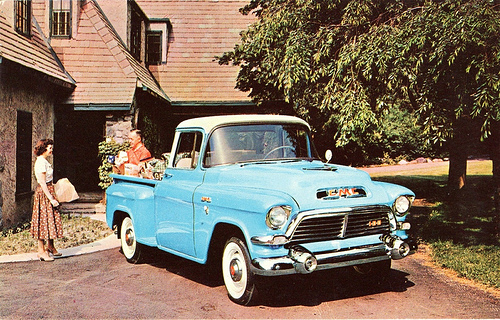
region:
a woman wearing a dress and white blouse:
[31, 135, 76, 262]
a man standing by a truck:
[111, 128, 148, 175]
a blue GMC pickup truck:
[103, 114, 413, 305]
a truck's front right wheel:
[220, 234, 265, 304]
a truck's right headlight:
[267, 204, 290, 229]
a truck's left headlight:
[391, 191, 413, 215]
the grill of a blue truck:
[251, 204, 402, 246]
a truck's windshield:
[205, 124, 322, 165]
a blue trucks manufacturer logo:
[316, 187, 365, 198]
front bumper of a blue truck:
[244, 239, 414, 274]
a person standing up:
[23, 136, 73, 263]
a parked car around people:
[98, 105, 420, 297]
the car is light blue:
[111, 113, 426, 294]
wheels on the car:
[114, 209, 414, 304]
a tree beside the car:
[243, 10, 493, 240]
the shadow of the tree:
[376, 173, 498, 236]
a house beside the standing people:
[9, 0, 281, 242]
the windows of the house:
[3, 2, 183, 63]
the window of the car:
[166, 127, 209, 174]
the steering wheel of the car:
[266, 145, 303, 158]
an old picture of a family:
[19, 17, 486, 306]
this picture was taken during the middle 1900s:
[4, 3, 434, 300]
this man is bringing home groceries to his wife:
[15, 102, 195, 267]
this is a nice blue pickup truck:
[110, 115, 415, 293]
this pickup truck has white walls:
[105, 208, 258, 314]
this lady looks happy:
[16, 123, 84, 264]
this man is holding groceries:
[96, 107, 158, 197]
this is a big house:
[13, 6, 296, 129]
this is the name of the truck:
[302, 176, 373, 206]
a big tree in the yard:
[247, 12, 484, 148]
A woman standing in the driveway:
[29, 135, 80, 262]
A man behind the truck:
[108, 126, 152, 171]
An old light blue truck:
[100, 110, 420, 309]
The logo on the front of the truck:
[314, 185, 369, 199]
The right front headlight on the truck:
[262, 203, 292, 229]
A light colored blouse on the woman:
[29, 154, 56, 186]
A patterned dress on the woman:
[26, 180, 63, 240]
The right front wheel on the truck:
[217, 234, 259, 306]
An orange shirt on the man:
[118, 145, 152, 170]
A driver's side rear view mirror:
[323, 145, 334, 162]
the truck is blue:
[64, 75, 449, 317]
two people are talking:
[20, 116, 167, 279]